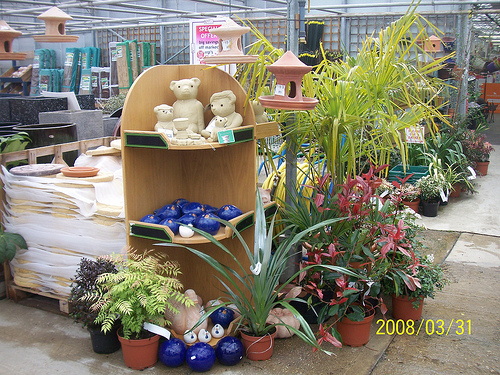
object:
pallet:
[7, 283, 72, 312]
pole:
[285, 116, 298, 282]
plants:
[77, 246, 195, 339]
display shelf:
[129, 197, 255, 245]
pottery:
[218, 204, 243, 221]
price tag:
[275, 83, 285, 96]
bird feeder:
[257, 47, 318, 110]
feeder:
[39, 68, 53, 93]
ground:
[0, 229, 498, 373]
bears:
[153, 104, 175, 132]